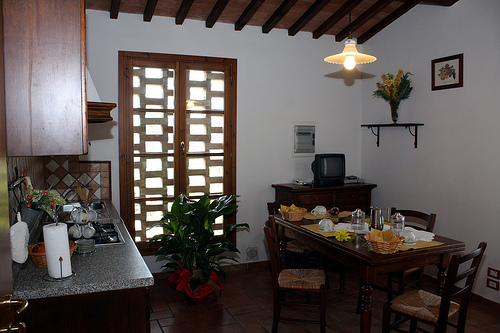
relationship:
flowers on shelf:
[364, 62, 424, 137] [354, 107, 440, 162]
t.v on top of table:
[310, 153, 346, 189] [273, 187, 478, 292]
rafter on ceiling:
[310, 3, 357, 38] [82, 0, 419, 45]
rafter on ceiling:
[261, 2, 293, 36] [82, 0, 419, 45]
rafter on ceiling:
[204, 2, 228, 30] [82, 0, 419, 45]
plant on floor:
[150, 185, 246, 306] [217, 279, 265, 324]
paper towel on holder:
[43, 225, 73, 262] [58, 257, 67, 279]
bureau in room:
[273, 179, 375, 221] [8, 0, 497, 327]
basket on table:
[367, 225, 406, 255] [268, 200, 448, 260]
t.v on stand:
[310, 153, 346, 189] [269, 177, 376, 217]